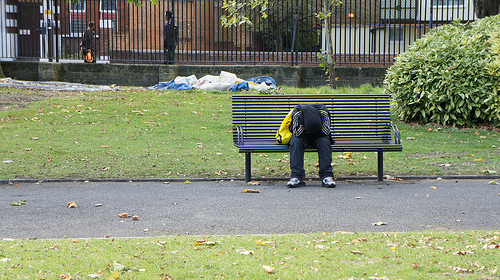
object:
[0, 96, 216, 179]
field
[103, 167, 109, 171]
leaf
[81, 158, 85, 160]
leaf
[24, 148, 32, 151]
leaf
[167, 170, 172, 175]
leaf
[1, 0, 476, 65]
metalfence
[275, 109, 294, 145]
yellow bag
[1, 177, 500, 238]
path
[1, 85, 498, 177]
grass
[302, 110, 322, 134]
hood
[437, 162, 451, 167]
leaf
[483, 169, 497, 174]
leaf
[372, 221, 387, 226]
leaf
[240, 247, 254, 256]
leaf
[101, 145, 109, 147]
leaf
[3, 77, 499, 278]
ground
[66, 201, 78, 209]
leaves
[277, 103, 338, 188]
man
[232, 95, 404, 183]
bench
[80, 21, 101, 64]
person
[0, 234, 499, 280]
grass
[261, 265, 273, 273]
leaves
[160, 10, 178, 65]
people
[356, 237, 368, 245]
leaves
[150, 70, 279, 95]
garbage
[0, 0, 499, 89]
background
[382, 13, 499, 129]
bush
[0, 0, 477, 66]
fence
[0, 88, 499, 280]
park